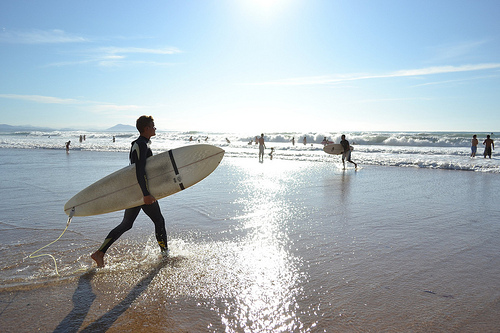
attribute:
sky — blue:
[0, 3, 498, 147]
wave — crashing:
[243, 128, 498, 148]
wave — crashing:
[218, 142, 498, 160]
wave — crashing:
[222, 153, 498, 173]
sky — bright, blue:
[0, 1, 500, 129]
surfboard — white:
[65, 144, 230, 231]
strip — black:
[168, 149, 181, 192]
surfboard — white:
[321, 141, 354, 156]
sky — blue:
[327, 8, 479, 81]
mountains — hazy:
[0, 117, 136, 134]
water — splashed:
[4, 132, 498, 330]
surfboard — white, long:
[64, 144, 224, 218]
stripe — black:
[167, 151, 184, 191]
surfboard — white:
[64, 143, 229, 213]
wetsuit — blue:
[97, 133, 174, 256]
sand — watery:
[2, 147, 499, 331]